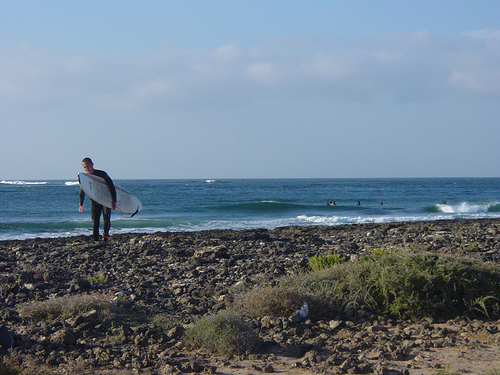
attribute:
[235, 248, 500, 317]
vegetation — green, brown, grass, partial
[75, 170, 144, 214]
surfboard — white, long, red, edged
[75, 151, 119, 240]
man — walking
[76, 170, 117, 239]
wetsuit — long sleeved, black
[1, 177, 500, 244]
ocean — blue, foamy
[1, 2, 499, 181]
sky — blue, lightly cloudy, partially cloudy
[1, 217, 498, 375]
ground — rocky, sandy, partial, edged, dirty, brown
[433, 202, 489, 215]
wave — breaking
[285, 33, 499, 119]
cloud — partial, white